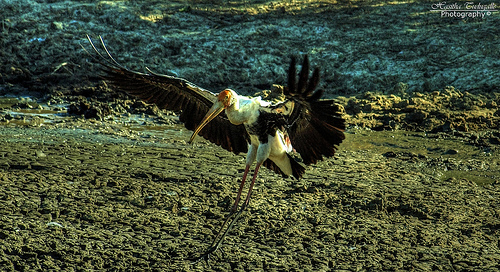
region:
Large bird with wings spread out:
[79, 31, 378, 267]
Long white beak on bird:
[184, 98, 230, 158]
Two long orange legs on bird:
[171, 147, 283, 267]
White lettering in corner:
[418, 3, 499, 27]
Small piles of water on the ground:
[7, 89, 214, 171]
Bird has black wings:
[59, 13, 244, 181]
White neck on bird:
[225, 95, 268, 140]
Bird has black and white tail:
[239, 129, 319, 199]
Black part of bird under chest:
[237, 107, 293, 152]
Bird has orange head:
[221, 88, 239, 114]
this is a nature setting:
[15, 10, 472, 230]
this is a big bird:
[75, 36, 345, 231]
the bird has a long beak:
[152, 83, 262, 135]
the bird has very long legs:
[222, 163, 301, 261]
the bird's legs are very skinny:
[210, 156, 294, 240]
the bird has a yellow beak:
[184, 106, 244, 143]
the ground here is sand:
[52, 156, 287, 260]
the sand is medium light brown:
[20, 150, 157, 264]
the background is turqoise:
[167, 7, 459, 102]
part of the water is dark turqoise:
[315, 6, 490, 81]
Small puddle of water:
[392, 131, 477, 153]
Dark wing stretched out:
[288, 65, 342, 168]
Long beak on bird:
[189, 102, 222, 139]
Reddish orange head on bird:
[216, 89, 236, 106]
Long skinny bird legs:
[213, 161, 253, 251]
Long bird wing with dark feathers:
[108, 66, 204, 122]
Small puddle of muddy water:
[441, 168, 494, 182]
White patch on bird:
[231, 101, 256, 122]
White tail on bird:
[268, 151, 303, 178]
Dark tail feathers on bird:
[288, 156, 306, 181]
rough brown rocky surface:
[7, 98, 494, 265]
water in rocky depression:
[335, 100, 492, 170]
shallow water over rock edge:
[5, 85, 175, 150]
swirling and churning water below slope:
[5, 5, 490, 95]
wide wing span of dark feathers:
[71, 26, 246, 156]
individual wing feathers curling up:
[71, 30, 116, 80]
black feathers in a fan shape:
[285, 51, 350, 161]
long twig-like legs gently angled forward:
[182, 160, 257, 270]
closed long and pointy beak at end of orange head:
[185, 86, 235, 141]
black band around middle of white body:
[235, 93, 293, 173]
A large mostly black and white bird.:
[79, 31, 346, 265]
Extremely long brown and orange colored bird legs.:
[191, 162, 269, 252]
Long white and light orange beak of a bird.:
[185, 101, 225, 144]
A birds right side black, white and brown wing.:
[78, 33, 250, 157]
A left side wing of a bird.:
[263, 56, 348, 166]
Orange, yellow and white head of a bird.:
[218, 87, 238, 109]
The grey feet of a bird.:
[191, 246, 224, 266]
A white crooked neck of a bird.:
[225, 103, 257, 123]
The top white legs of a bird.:
[245, 140, 272, 166]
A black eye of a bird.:
[222, 93, 230, 98]